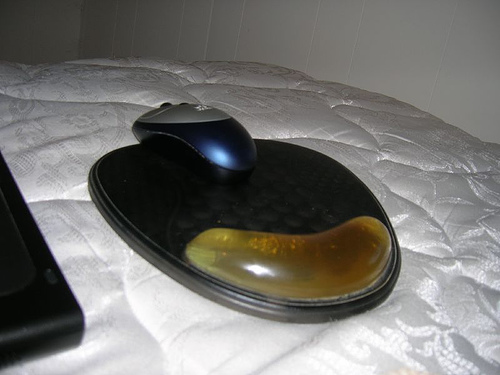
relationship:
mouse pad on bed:
[87, 138, 401, 324] [4, 59, 486, 370]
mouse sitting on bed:
[131, 102, 258, 184] [20, 70, 125, 124]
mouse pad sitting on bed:
[87, 138, 401, 324] [20, 70, 125, 124]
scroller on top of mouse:
[158, 100, 174, 109] [135, 94, 267, 185]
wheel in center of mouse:
[152, 100, 175, 107] [130, 90, 258, 177]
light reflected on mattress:
[141, 284, 404, 369] [2, 59, 492, 362]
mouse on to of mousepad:
[131, 102, 258, 184] [164, 188, 373, 310]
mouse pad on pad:
[87, 138, 401, 324] [91, 137, 402, 319]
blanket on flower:
[6, 50, 496, 367] [436, 186, 496, 265]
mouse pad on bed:
[87, 132, 400, 312] [4, 59, 486, 370]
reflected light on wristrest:
[229, 260, 279, 281] [87, 139, 400, 326]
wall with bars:
[132, 1, 499, 123] [156, 4, 246, 55]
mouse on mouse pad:
[141, 92, 261, 188] [87, 138, 401, 324]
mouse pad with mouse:
[87, 138, 401, 324] [141, 92, 261, 188]